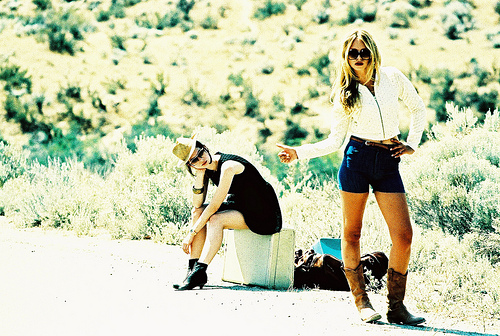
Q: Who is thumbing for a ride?
A: The woman on the right.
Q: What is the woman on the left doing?
A: Sitting down.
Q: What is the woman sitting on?
A: A white suitcase.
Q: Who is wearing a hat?
A: The woman sitting down.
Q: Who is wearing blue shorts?
A: The woman on the right.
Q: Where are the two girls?
A: On the side of a road.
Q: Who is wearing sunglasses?
A: Both women.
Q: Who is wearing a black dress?
A: The woman sitting down.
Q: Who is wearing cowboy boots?
A: The woman on the right.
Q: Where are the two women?
A: On the side of a road.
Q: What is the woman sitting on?
A: A suitcase.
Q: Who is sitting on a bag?
A: A woman.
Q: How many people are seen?
A: 2.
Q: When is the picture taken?
A: Daytime.